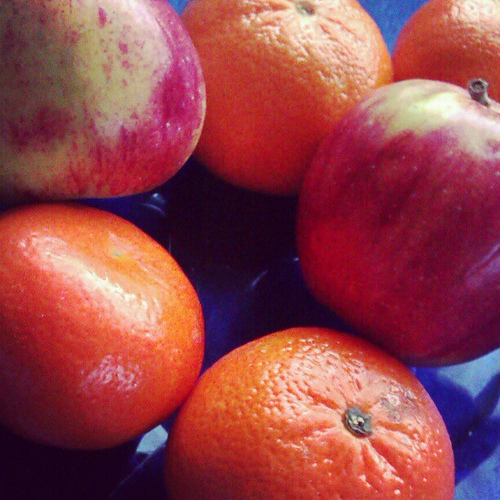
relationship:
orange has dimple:
[162, 321, 467, 498] [344, 409, 371, 436]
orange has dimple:
[175, 3, 401, 196] [290, 4, 320, 22]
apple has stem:
[291, 76, 499, 372] [466, 74, 494, 112]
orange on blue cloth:
[3, 208, 211, 451] [7, 2, 493, 498]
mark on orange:
[296, 380, 341, 414] [162, 321, 467, 498]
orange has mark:
[162, 321, 467, 498] [296, 380, 341, 414]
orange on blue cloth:
[162, 321, 467, 498] [7, 2, 493, 498]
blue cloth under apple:
[7, 2, 493, 498] [291, 76, 499, 372]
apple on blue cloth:
[1, 2, 205, 203] [7, 2, 493, 498]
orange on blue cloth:
[175, 3, 401, 196] [7, 2, 493, 498]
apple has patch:
[291, 76, 499, 372] [362, 80, 494, 167]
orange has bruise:
[162, 321, 467, 498] [376, 385, 433, 422]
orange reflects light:
[3, 208, 211, 451] [29, 230, 180, 339]